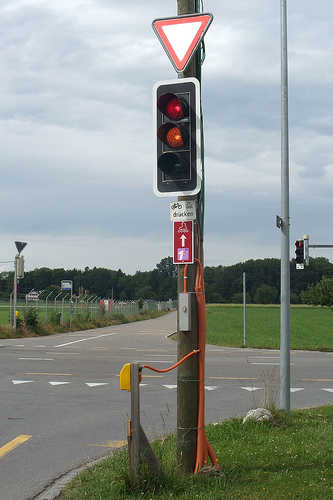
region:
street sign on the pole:
[142, 10, 213, 69]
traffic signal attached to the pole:
[148, 77, 199, 194]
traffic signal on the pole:
[151, 78, 206, 203]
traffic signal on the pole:
[292, 235, 302, 259]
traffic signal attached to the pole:
[294, 238, 307, 263]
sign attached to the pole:
[169, 221, 197, 262]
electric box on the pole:
[113, 363, 131, 389]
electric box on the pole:
[174, 292, 191, 332]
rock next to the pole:
[240, 404, 276, 425]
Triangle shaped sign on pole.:
[147, 7, 221, 73]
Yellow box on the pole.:
[116, 361, 137, 392]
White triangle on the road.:
[80, 376, 109, 392]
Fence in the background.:
[1, 282, 177, 333]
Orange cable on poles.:
[139, 255, 222, 472]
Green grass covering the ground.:
[206, 301, 331, 350]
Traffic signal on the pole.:
[148, 73, 207, 205]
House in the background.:
[23, 283, 46, 302]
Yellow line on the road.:
[0, 424, 32, 468]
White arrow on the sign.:
[177, 232, 188, 248]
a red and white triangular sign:
[146, 12, 212, 72]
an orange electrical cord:
[138, 217, 219, 472]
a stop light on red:
[293, 234, 312, 273]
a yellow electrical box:
[118, 362, 132, 392]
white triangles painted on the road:
[10, 379, 331, 396]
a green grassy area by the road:
[61, 405, 331, 498]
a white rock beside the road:
[242, 408, 274, 421]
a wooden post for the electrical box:
[129, 361, 166, 485]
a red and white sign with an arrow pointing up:
[173, 220, 192, 262]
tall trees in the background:
[0, 257, 331, 304]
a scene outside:
[3, 3, 327, 497]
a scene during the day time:
[8, 2, 317, 496]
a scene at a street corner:
[1, 3, 326, 497]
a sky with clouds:
[2, 4, 329, 282]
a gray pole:
[264, 0, 303, 433]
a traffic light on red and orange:
[138, 4, 231, 484]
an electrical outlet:
[106, 342, 176, 498]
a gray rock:
[231, 395, 286, 433]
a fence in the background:
[4, 261, 184, 345]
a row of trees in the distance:
[3, 248, 330, 309]